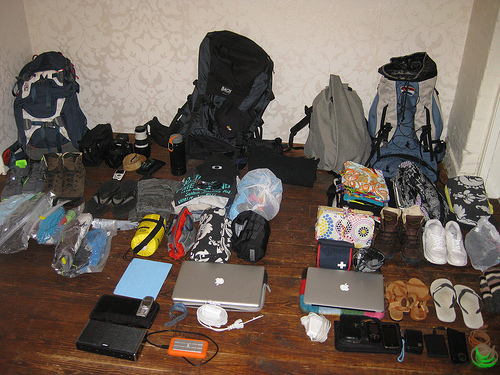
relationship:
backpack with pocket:
[161, 28, 279, 179] [182, 90, 222, 137]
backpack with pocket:
[161, 28, 279, 179] [246, 87, 276, 121]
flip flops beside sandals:
[427, 274, 487, 331] [385, 275, 431, 321]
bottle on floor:
[165, 133, 186, 176] [5, 123, 499, 375]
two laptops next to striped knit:
[169, 251, 386, 324] [296, 268, 381, 317]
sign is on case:
[334, 259, 351, 272] [310, 237, 356, 270]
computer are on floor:
[171, 260, 268, 312] [4, 268, 74, 368]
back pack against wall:
[34, 43, 107, 173] [34, 7, 494, 185]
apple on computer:
[213, 275, 225, 286] [170, 257, 268, 312]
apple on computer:
[340, 281, 350, 292] [301, 265, 386, 315]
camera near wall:
[110, 132, 133, 164] [22, 3, 473, 145]